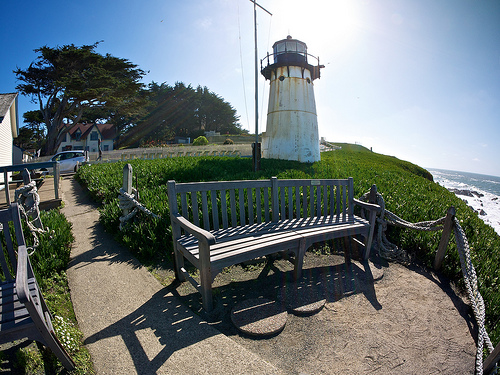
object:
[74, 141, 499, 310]
ground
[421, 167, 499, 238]
ocean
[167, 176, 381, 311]
bench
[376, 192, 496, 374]
rope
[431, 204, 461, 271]
post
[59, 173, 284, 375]
sidewalk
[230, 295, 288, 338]
step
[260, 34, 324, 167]
lighthouse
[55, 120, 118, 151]
house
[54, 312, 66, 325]
flower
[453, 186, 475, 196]
rock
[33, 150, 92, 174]
car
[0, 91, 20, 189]
building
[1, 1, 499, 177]
sky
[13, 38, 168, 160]
tree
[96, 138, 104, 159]
person